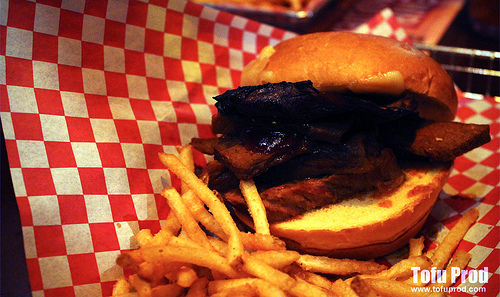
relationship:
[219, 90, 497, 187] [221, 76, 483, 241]
meat in burger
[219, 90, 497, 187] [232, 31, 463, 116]
meat on bun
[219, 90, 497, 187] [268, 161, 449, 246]
meat on bun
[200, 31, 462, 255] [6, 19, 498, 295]
sandwich on wrapper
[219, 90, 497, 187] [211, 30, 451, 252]
meat in bun